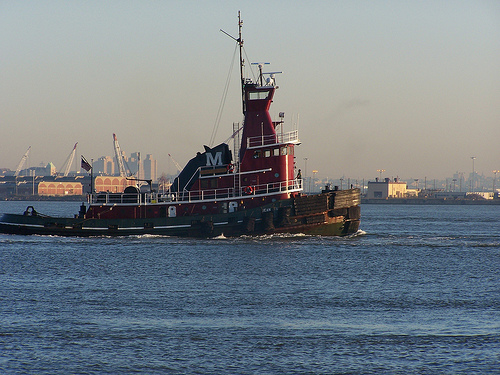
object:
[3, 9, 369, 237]
ship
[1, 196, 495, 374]
ocean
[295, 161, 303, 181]
person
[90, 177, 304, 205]
rails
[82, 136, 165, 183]
buildings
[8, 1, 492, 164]
sky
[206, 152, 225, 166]
m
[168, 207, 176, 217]
door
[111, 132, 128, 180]
crane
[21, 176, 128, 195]
buildings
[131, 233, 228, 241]
foam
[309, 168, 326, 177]
lights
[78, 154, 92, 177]
flag